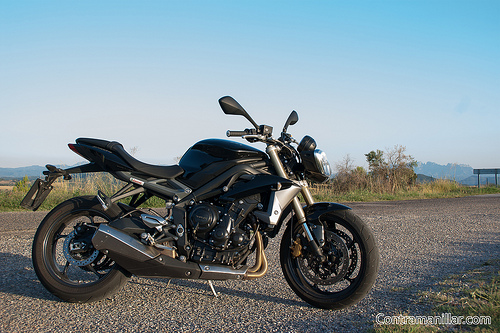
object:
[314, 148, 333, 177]
headlight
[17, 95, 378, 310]
motorcycle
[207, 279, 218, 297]
kickstand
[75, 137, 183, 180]
seat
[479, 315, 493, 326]
letters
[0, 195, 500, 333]
road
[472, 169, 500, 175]
sign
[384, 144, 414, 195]
trees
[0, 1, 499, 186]
sky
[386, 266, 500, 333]
grass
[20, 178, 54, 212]
plate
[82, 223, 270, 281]
muffler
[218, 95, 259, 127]
mirrors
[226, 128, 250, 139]
handlebars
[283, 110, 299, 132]
mirrors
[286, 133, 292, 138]
handlebars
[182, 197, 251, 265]
engine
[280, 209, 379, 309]
tires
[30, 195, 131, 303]
tires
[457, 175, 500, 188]
mountains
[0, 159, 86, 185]
mountains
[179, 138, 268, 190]
tank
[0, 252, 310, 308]
shadow